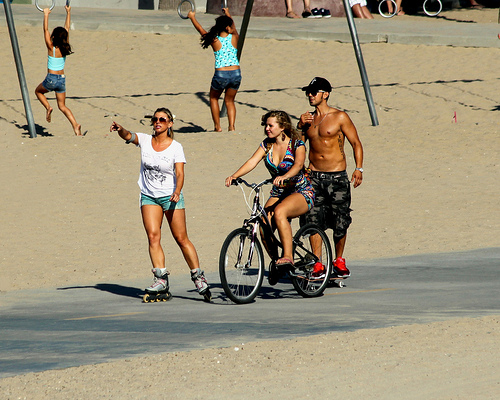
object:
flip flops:
[266, 256, 301, 271]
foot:
[138, 278, 178, 306]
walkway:
[0, 237, 499, 380]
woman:
[105, 101, 217, 307]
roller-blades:
[80, 276, 221, 323]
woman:
[218, 103, 322, 274]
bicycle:
[211, 170, 338, 308]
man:
[288, 72, 369, 290]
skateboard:
[292, 271, 360, 290]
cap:
[297, 74, 339, 93]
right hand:
[296, 109, 319, 129]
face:
[303, 88, 328, 108]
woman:
[27, 3, 89, 143]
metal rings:
[30, 0, 58, 15]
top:
[210, 30, 246, 71]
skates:
[185, 263, 215, 307]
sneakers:
[327, 254, 353, 280]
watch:
[351, 164, 367, 174]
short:
[37, 70, 73, 100]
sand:
[12, 141, 113, 161]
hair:
[256, 106, 313, 156]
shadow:
[56, 276, 142, 299]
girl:
[27, 4, 95, 140]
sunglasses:
[300, 86, 330, 98]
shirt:
[131, 128, 191, 201]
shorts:
[135, 188, 190, 215]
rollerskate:
[138, 263, 175, 305]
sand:
[15, 160, 98, 264]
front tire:
[213, 221, 268, 308]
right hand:
[223, 172, 240, 190]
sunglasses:
[148, 114, 173, 124]